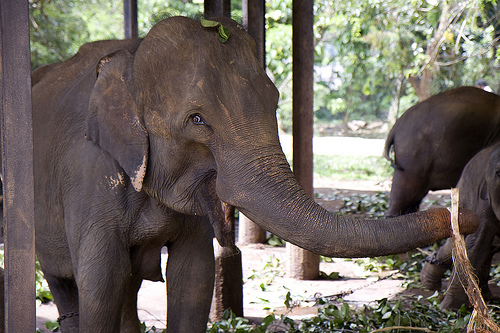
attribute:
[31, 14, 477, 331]
elephant — brown, here, outdoors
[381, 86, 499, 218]
elephant — here, brown, outdoors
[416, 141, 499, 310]
elephant — here, outdoors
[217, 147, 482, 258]
trunk — raised, long, wrinkly, brown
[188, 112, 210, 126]
right eye — brown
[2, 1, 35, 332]
beam — brown, tall, metal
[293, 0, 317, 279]
beam — metal, brown, tall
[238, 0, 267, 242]
beam — brown, metal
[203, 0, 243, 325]
beam — brown, metal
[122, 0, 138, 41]
beam — brown, metal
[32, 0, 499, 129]
leaves — green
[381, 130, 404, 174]
tail — wagging, short, black, brown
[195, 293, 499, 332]
leaves — green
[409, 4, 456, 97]
branch — brown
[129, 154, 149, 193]
skin — pink, white, brown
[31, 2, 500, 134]
trees — leafy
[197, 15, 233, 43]
leaves — green